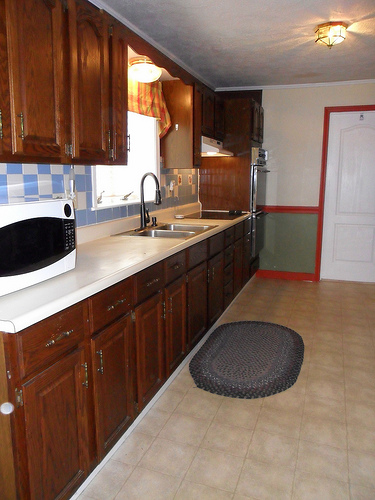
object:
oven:
[250, 145, 268, 257]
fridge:
[260, 146, 278, 256]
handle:
[94, 188, 106, 209]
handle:
[121, 188, 134, 201]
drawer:
[10, 309, 83, 376]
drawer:
[86, 277, 133, 330]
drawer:
[135, 262, 162, 303]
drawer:
[163, 252, 189, 283]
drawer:
[223, 227, 236, 246]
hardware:
[207, 269, 215, 281]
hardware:
[160, 298, 169, 319]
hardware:
[80, 356, 91, 387]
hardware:
[8, 381, 24, 407]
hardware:
[44, 328, 77, 346]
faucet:
[138, 169, 163, 227]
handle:
[141, 208, 151, 223]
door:
[320, 107, 372, 283]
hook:
[358, 112, 367, 121]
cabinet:
[1, 1, 129, 163]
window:
[91, 112, 162, 207]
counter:
[89, 204, 202, 292]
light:
[125, 58, 161, 87]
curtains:
[124, 74, 175, 137]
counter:
[0, 229, 146, 329]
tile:
[282, 287, 328, 314]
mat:
[188, 313, 305, 400]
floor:
[229, 276, 374, 497]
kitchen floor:
[161, 396, 317, 478]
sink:
[138, 212, 218, 245]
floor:
[164, 424, 269, 497]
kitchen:
[17, 1, 375, 366]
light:
[309, 19, 350, 52]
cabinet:
[19, 348, 85, 495]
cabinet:
[85, 311, 142, 438]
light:
[88, 110, 158, 204]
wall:
[252, 201, 320, 275]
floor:
[280, 274, 371, 385]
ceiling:
[84, 2, 372, 92]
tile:
[183, 447, 244, 491]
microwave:
[0, 193, 78, 293]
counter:
[3, 210, 250, 334]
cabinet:
[21, 347, 89, 493]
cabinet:
[135, 288, 167, 396]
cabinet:
[163, 272, 187, 365]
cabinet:
[186, 260, 207, 341]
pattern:
[185, 404, 373, 500]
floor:
[83, 272, 374, 499]